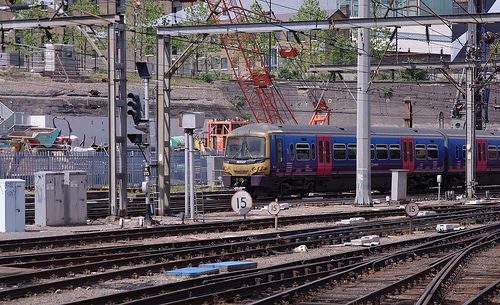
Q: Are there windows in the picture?
A: Yes, there is a window.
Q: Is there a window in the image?
A: Yes, there is a window.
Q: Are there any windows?
A: Yes, there is a window.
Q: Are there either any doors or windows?
A: Yes, there is a window.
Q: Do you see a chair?
A: No, there are no chairs.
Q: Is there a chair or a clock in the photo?
A: No, there are no chairs or clocks.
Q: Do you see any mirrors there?
A: No, there are no mirrors.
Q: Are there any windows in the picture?
A: Yes, there is a window.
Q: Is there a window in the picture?
A: Yes, there is a window.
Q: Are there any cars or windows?
A: Yes, there is a window.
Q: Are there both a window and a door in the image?
A: Yes, there are both a window and a door.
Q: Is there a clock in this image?
A: No, there are no clocks.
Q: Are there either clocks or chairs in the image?
A: No, there are no clocks or chairs.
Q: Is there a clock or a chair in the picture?
A: No, there are no clocks or chairs.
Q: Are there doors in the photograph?
A: Yes, there are doors.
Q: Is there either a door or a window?
A: Yes, there are doors.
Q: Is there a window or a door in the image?
A: Yes, there are doors.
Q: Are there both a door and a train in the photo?
A: Yes, there are both a door and a train.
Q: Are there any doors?
A: Yes, there are doors.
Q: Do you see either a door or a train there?
A: Yes, there are doors.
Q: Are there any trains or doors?
A: Yes, there are doors.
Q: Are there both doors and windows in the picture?
A: Yes, there are both doors and a window.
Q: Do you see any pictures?
A: No, there are no pictures.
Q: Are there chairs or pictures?
A: No, there are no pictures or chairs.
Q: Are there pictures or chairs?
A: No, there are no pictures or chairs.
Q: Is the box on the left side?
A: Yes, the box is on the left of the image.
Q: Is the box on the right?
A: No, the box is on the left of the image.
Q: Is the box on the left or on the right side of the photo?
A: The box is on the left of the image.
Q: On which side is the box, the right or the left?
A: The box is on the left of the image.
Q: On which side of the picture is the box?
A: The box is on the left of the image.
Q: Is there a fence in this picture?
A: Yes, there is a fence.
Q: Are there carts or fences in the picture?
A: Yes, there is a fence.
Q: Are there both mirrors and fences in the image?
A: No, there is a fence but no mirrors.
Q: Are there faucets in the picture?
A: No, there are no faucets.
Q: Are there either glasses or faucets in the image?
A: No, there are no faucets or glasses.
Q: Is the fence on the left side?
A: Yes, the fence is on the left of the image.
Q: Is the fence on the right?
A: No, the fence is on the left of the image.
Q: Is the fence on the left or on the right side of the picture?
A: The fence is on the left of the image.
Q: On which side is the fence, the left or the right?
A: The fence is on the left of the image.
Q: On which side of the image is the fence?
A: The fence is on the left of the image.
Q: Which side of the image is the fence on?
A: The fence is on the left of the image.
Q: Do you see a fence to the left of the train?
A: Yes, there is a fence to the left of the train.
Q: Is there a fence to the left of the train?
A: Yes, there is a fence to the left of the train.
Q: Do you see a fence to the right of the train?
A: No, the fence is to the left of the train.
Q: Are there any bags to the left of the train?
A: No, there is a fence to the left of the train.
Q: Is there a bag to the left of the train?
A: No, there is a fence to the left of the train.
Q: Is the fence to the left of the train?
A: Yes, the fence is to the left of the train.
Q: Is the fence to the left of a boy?
A: No, the fence is to the left of the train.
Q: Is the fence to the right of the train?
A: No, the fence is to the left of the train.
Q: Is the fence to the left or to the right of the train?
A: The fence is to the left of the train.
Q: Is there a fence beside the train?
A: Yes, there is a fence beside the train.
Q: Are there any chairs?
A: No, there are no chairs.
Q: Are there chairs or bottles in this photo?
A: No, there are no chairs or bottles.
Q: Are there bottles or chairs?
A: No, there are no chairs or bottles.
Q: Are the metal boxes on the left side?
A: Yes, the boxes are on the left of the image.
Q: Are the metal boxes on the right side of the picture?
A: No, the boxes are on the left of the image.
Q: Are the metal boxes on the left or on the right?
A: The boxes are on the left of the image.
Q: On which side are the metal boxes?
A: The boxes are on the left of the image.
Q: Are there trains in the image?
A: Yes, there is a train.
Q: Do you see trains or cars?
A: Yes, there is a train.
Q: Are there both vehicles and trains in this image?
A: Yes, there are both a train and a vehicle.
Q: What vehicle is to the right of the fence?
A: The vehicle is a train.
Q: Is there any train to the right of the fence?
A: Yes, there is a train to the right of the fence.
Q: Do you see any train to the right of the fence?
A: Yes, there is a train to the right of the fence.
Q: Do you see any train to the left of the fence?
A: No, the train is to the right of the fence.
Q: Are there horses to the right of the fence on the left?
A: No, there is a train to the right of the fence.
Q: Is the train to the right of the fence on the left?
A: Yes, the train is to the right of the fence.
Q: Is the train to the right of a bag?
A: No, the train is to the right of the fence.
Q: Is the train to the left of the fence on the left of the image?
A: No, the train is to the right of the fence.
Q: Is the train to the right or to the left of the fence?
A: The train is to the right of the fence.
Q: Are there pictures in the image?
A: No, there are no pictures.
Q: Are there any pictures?
A: No, there are no pictures.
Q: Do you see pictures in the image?
A: No, there are no pictures.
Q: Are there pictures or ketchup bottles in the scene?
A: No, there are no pictures or ketchup bottles.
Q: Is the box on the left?
A: Yes, the box is on the left of the image.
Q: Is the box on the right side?
A: No, the box is on the left of the image.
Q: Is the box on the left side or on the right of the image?
A: The box is on the left of the image.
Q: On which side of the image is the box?
A: The box is on the left of the image.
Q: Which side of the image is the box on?
A: The box is on the left of the image.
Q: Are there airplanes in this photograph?
A: No, there are no airplanes.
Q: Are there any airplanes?
A: No, there are no airplanes.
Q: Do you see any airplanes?
A: No, there are no airplanes.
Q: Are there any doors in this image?
A: Yes, there are doors.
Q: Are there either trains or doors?
A: Yes, there are doors.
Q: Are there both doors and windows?
A: Yes, there are both doors and a window.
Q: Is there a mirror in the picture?
A: No, there are no mirrors.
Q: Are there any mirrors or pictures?
A: No, there are no mirrors or pictures.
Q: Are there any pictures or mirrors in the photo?
A: No, there are no mirrors or pictures.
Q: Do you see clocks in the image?
A: No, there are no clocks.